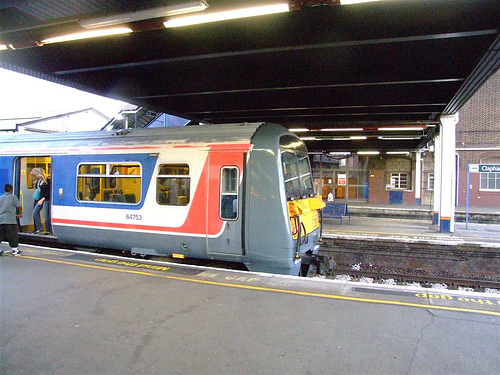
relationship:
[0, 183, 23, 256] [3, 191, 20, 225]
boy wearing shirt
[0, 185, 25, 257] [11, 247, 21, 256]
boy wearing sneaker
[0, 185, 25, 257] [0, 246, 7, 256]
boy wearing sneaker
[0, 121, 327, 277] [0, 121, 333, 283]
paint on train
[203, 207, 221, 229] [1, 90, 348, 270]
red paint on train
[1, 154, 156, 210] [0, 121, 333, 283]
blue paint on train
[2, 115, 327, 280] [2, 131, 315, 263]
paint on train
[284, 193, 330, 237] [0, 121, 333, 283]
paint on train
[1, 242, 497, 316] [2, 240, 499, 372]
stripe on platform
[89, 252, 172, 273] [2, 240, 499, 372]
lettering on platform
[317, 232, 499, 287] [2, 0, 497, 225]
train tracks near a station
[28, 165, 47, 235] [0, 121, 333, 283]
woman getting off a train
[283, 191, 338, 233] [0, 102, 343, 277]
bumper on a train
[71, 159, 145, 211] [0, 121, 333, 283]
window on a train